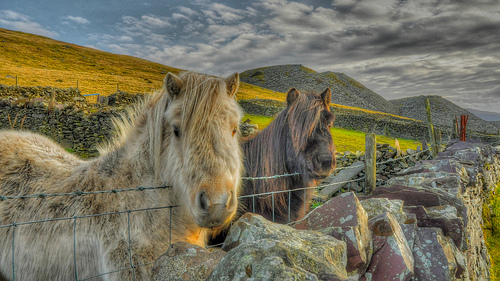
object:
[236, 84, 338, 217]
horse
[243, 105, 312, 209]
hair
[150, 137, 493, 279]
wall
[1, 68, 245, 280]
horse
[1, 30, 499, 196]
hillside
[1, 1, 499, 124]
sky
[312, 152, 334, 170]
nose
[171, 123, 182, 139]
right eye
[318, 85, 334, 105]
left ear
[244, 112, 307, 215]
neck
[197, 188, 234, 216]
nose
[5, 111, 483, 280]
fence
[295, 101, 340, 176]
face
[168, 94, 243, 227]
face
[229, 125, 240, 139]
left eye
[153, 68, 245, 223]
head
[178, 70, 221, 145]
hair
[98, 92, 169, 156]
hair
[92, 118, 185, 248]
neck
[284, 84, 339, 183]
head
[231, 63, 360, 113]
hill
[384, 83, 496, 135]
hill